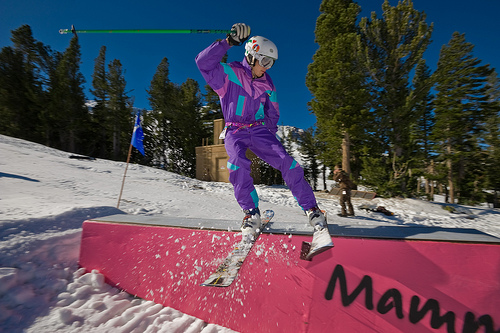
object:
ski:
[305, 227, 337, 259]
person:
[197, 20, 327, 236]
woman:
[193, 35, 324, 234]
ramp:
[77, 212, 499, 332]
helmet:
[243, 35, 279, 61]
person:
[332, 164, 357, 217]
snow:
[398, 203, 414, 219]